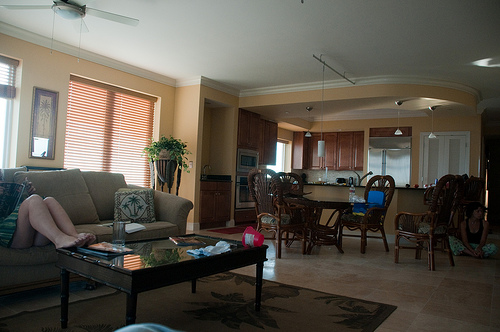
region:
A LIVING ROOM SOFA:
[1, 165, 198, 300]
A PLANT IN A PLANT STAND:
[144, 133, 194, 193]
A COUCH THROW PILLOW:
[109, 183, 159, 225]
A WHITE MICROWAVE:
[234, 143, 264, 176]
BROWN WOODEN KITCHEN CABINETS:
[299, 127, 369, 174]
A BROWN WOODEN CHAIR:
[389, 169, 457, 273]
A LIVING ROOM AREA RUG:
[2, 265, 400, 328]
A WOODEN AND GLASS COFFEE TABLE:
[54, 230, 271, 329]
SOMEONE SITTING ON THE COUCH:
[2, 187, 100, 253]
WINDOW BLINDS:
[62, 70, 163, 190]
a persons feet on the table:
[11, 175, 93, 261]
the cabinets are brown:
[290, 122, 386, 177]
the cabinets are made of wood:
[280, 122, 379, 178]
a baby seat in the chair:
[342, 170, 393, 248]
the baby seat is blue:
[328, 171, 400, 228]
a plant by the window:
[115, 106, 197, 200]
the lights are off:
[255, 106, 444, 145]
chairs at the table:
[238, 150, 402, 256]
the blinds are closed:
[43, 70, 164, 178]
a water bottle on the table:
[343, 179, 369, 207]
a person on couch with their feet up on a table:
[4, 179, 96, 251]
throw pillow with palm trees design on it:
[111, 186, 157, 225]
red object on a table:
[239, 224, 265, 249]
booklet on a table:
[170, 232, 211, 247]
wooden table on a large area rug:
[0, 231, 399, 331]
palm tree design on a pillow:
[118, 192, 148, 218]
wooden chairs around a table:
[244, 166, 398, 258]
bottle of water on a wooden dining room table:
[345, 181, 358, 202]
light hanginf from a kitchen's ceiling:
[393, 99, 403, 136]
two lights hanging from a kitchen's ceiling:
[392, 97, 438, 142]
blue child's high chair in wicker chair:
[349, 190, 380, 218]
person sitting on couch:
[2, 180, 79, 262]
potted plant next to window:
[150, 135, 185, 167]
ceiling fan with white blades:
[4, 2, 127, 39]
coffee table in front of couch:
[66, 234, 270, 314]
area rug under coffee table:
[4, 259, 405, 328]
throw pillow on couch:
[115, 187, 152, 222]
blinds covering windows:
[63, 78, 153, 178]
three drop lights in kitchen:
[299, 109, 439, 143]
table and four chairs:
[251, 155, 453, 265]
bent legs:
[14, 185, 106, 265]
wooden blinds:
[66, 75, 168, 186]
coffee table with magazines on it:
[65, 209, 326, 327]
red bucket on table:
[239, 221, 286, 301]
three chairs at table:
[245, 147, 415, 277]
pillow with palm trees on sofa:
[112, 183, 174, 236]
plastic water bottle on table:
[342, 175, 374, 219]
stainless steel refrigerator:
[364, 132, 416, 194]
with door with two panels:
[421, 130, 480, 197]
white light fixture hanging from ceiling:
[298, 50, 343, 189]